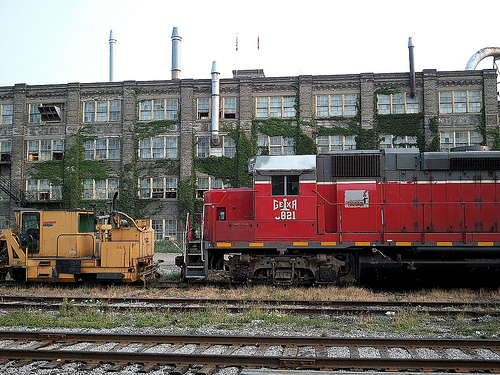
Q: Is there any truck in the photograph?
A: No, there are no trucks.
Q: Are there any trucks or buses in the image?
A: No, there are no trucks or buses.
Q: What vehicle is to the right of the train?
A: The vehicle is a car.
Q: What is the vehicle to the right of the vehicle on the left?
A: The vehicle is a car.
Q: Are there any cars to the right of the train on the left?
A: Yes, there is a car to the right of the train.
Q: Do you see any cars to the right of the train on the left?
A: Yes, there is a car to the right of the train.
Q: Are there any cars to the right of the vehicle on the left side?
A: Yes, there is a car to the right of the train.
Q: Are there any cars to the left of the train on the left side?
A: No, the car is to the right of the train.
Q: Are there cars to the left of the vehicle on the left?
A: No, the car is to the right of the train.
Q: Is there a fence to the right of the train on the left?
A: No, there is a car to the right of the train.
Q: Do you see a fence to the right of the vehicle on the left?
A: No, there is a car to the right of the train.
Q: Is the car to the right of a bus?
A: No, the car is to the right of the train.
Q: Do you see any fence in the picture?
A: No, there are no fences.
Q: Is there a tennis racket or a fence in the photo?
A: No, there are no fences or rackets.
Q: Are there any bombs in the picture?
A: No, there are no bombs.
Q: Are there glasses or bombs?
A: No, there are no bombs or glasses.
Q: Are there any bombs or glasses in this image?
A: No, there are no bombs or glasses.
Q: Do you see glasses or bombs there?
A: No, there are no bombs or glasses.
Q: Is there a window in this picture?
A: Yes, there are windows.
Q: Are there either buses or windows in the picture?
A: Yes, there are windows.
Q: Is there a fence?
A: No, there are no fences.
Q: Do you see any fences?
A: No, there are no fences.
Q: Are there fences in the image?
A: No, there are no fences.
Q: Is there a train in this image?
A: Yes, there is a train.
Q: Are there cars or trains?
A: Yes, there is a train.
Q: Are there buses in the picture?
A: No, there are no buses.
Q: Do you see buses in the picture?
A: No, there are no buses.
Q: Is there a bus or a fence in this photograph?
A: No, there are no buses or fences.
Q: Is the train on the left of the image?
A: Yes, the train is on the left of the image.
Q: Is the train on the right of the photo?
A: No, the train is on the left of the image.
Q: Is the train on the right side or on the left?
A: The train is on the left of the image.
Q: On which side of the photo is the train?
A: The train is on the left of the image.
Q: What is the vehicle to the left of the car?
A: The vehicle is a train.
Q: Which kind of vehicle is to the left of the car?
A: The vehicle is a train.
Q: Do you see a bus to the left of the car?
A: No, there is a train to the left of the car.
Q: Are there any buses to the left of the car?
A: No, there is a train to the left of the car.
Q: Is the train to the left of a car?
A: Yes, the train is to the left of a car.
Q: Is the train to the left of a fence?
A: No, the train is to the left of a car.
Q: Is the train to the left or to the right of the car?
A: The train is to the left of the car.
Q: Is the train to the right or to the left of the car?
A: The train is to the left of the car.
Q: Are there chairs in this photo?
A: No, there are no chairs.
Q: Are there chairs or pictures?
A: No, there are no chairs or pictures.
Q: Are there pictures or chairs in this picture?
A: No, there are no chairs or pictures.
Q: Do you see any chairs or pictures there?
A: No, there are no chairs or pictures.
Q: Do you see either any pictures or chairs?
A: No, there are no chairs or pictures.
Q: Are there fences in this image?
A: No, there are no fences.